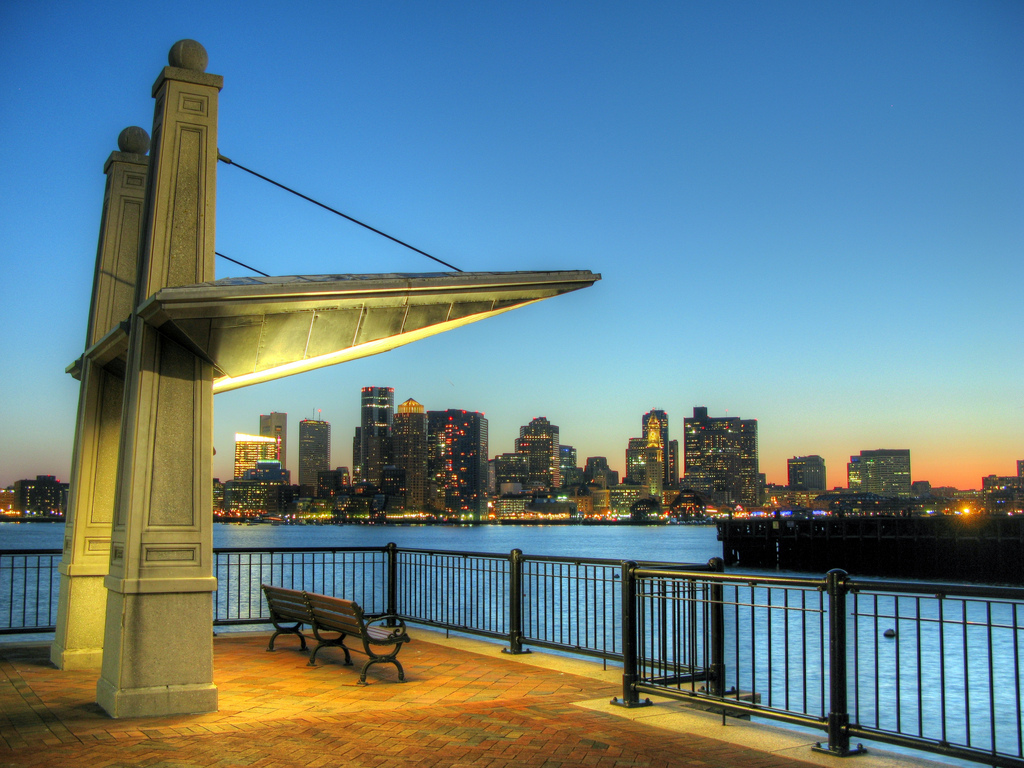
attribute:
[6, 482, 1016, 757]
river — calm , blue 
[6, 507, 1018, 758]
railing — metal 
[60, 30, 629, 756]
structure — unique  , covered 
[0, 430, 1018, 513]
skyline — pinkish , orange 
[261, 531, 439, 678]
bench — wooden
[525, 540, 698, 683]
water —  light blue 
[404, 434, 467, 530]
building — dark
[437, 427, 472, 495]
lights — red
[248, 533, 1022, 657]
rails — black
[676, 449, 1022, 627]
boat — dark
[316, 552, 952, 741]
fence — black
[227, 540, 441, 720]
bench — black and wood